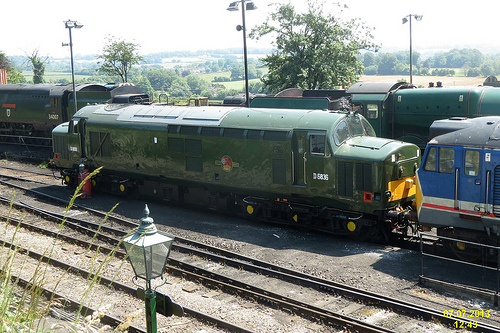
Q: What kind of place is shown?
A: It is a railroad.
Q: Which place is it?
A: It is a railroad.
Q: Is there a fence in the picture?
A: No, there are no fences.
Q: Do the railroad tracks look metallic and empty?
A: Yes, the railroad tracks are metallic and empty.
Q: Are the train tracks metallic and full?
A: No, the train tracks are metallic but empty.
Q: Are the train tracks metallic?
A: Yes, the train tracks are metallic.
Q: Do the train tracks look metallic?
A: Yes, the train tracks are metallic.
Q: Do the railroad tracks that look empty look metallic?
A: Yes, the tracks are metallic.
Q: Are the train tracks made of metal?
A: Yes, the train tracks are made of metal.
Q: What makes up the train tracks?
A: The train tracks are made of metal.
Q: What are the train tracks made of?
A: The train tracks are made of metal.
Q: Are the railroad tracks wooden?
A: No, the railroad tracks are metallic.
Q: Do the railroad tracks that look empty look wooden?
A: No, the train tracks are metallic.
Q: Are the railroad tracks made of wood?
A: No, the railroad tracks are made of metal.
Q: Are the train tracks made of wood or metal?
A: The train tracks are made of metal.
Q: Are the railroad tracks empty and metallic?
A: Yes, the railroad tracks are empty and metallic.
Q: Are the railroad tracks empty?
A: Yes, the railroad tracks are empty.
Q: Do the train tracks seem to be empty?
A: Yes, the train tracks are empty.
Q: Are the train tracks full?
A: No, the train tracks are empty.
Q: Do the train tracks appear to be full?
A: No, the train tracks are empty.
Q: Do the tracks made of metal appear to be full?
A: No, the tracks are empty.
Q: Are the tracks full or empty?
A: The tracks are empty.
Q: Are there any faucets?
A: No, there are no faucets.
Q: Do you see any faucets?
A: No, there are no faucets.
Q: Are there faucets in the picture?
A: No, there are no faucets.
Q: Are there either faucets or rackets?
A: No, there are no faucets or rackets.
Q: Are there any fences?
A: No, there are no fences.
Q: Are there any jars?
A: No, there are no jars.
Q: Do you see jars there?
A: No, there are no jars.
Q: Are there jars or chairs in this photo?
A: No, there are no jars or chairs.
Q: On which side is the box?
A: The box is on the left of the image.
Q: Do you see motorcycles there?
A: No, there are no motorcycles.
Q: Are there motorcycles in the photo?
A: No, there are no motorcycles.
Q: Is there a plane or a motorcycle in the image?
A: No, there are no motorcycles or airplanes.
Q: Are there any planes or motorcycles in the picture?
A: No, there are no motorcycles or planes.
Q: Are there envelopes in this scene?
A: No, there are no envelopes.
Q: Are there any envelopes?
A: No, there are no envelopes.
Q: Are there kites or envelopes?
A: No, there are no envelopes or kites.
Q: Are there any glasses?
A: No, there are no glasses.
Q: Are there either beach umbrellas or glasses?
A: No, there are no glasses or beach umbrellas.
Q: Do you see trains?
A: Yes, there is a train.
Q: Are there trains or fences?
A: Yes, there is a train.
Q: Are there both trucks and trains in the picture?
A: No, there is a train but no trucks.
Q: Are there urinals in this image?
A: No, there are no urinals.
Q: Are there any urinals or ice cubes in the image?
A: No, there are no urinals or ice cubes.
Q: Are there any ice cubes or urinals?
A: No, there are no urinals or ice cubes.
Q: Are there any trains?
A: Yes, there is a train.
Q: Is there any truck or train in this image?
A: Yes, there is a train.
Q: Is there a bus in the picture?
A: No, there are no buses.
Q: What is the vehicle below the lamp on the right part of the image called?
A: The vehicle is a train.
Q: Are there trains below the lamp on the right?
A: Yes, there is a train below the lamp.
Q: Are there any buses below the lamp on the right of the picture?
A: No, there is a train below the lamp.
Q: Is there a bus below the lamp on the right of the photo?
A: No, there is a train below the lamp.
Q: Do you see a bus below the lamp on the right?
A: No, there is a train below the lamp.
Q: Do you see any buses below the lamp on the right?
A: No, there is a train below the lamp.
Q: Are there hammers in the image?
A: No, there are no hammers.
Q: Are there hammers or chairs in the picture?
A: No, there are no hammers or chairs.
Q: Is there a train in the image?
A: Yes, there is a train.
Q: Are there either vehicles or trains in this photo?
A: Yes, there is a train.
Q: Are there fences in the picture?
A: No, there are no fences.